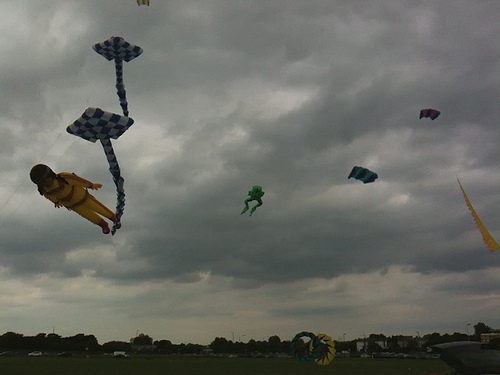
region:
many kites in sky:
[29, 25, 470, 333]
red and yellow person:
[47, 167, 114, 245]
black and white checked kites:
[72, 31, 141, 178]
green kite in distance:
[233, 190, 277, 240]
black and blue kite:
[340, 151, 392, 179]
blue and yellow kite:
[404, 103, 456, 123]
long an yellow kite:
[444, 171, 493, 256]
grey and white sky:
[244, 48, 357, 218]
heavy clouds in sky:
[250, 13, 354, 213]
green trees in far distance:
[19, 312, 284, 344]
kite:
[19, 139, 160, 237]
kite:
[232, 169, 284, 220]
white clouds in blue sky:
[321, 245, 346, 262]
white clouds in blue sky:
[364, 233, 396, 256]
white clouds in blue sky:
[200, 267, 259, 318]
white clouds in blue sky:
[172, 52, 220, 94]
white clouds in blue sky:
[162, 163, 223, 198]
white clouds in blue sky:
[243, 4, 278, 41]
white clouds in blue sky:
[290, 52, 347, 89]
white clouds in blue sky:
[164, 30, 234, 95]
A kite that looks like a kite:
[229, 174, 287, 220]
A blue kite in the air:
[333, 144, 385, 195]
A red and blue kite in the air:
[410, 97, 444, 126]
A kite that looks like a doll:
[17, 147, 134, 260]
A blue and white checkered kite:
[73, 116, 148, 231]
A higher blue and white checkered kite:
[86, 29, 159, 98]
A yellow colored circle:
[311, 328, 353, 374]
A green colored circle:
[283, 319, 316, 367]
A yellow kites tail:
[446, 165, 499, 279]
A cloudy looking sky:
[127, 115, 465, 316]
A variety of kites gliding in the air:
[20, 25, 451, 283]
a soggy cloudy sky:
[183, 232, 257, 277]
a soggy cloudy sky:
[260, 254, 310, 281]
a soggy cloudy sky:
[301, 219, 365, 244]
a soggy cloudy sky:
[302, 62, 359, 109]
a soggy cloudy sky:
[318, 111, 356, 131]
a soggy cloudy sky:
[331, 217, 375, 265]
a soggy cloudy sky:
[380, 267, 423, 303]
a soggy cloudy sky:
[440, 216, 467, 249]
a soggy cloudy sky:
[159, 238, 201, 273]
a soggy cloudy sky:
[72, 254, 135, 292]